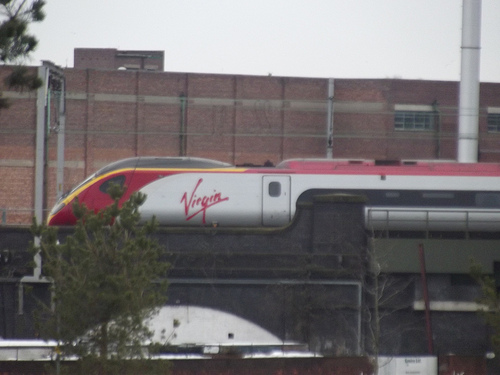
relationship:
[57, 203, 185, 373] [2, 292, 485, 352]
tree next to train tracks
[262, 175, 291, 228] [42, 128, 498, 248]
door on train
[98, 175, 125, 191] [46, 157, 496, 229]
window on train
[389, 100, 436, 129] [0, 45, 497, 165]
window on building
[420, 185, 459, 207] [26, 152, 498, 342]
window on train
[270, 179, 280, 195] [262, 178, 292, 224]
window on door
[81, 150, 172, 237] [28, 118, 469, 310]
window on train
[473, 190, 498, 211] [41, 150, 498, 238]
window on train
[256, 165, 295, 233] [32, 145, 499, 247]
door on train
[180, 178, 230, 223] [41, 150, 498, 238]
logo on train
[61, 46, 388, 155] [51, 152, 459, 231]
building behind train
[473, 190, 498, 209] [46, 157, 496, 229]
window on train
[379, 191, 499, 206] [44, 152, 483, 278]
windows on train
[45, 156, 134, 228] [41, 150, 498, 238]
nose of train